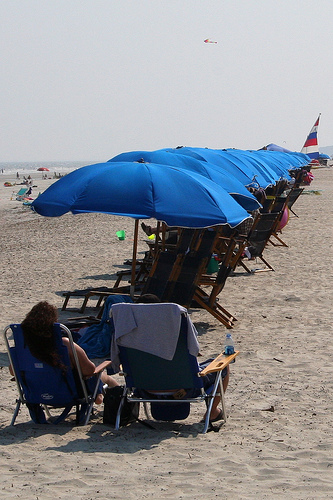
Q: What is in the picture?
A: Umbrellas.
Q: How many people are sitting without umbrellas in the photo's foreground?
A: Two.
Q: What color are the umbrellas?
A: Blue.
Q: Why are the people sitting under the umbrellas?
A: For shade.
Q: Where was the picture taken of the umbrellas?
A: The beach.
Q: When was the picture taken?
A: Daytime.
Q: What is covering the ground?
A: Sand.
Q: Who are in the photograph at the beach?
A: People.